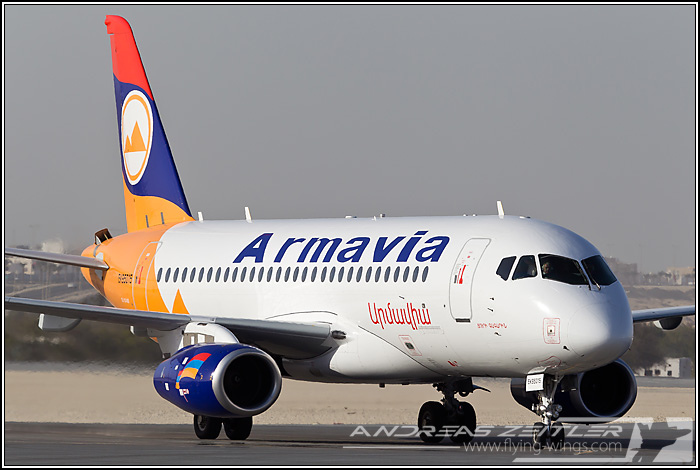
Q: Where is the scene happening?
A: At an airport.